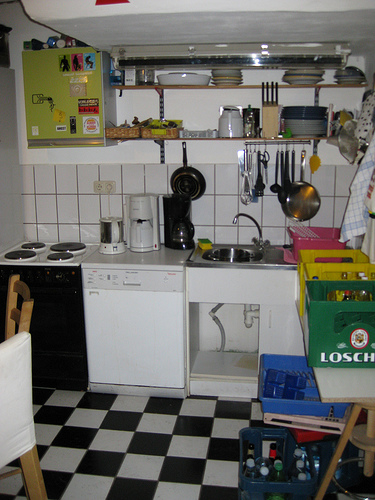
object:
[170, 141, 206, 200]
frying pan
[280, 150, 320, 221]
pot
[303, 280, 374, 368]
crate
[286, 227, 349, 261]
dish rack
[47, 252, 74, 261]
burner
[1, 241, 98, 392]
stove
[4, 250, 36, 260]
burner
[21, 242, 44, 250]
burner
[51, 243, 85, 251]
burner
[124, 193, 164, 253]
coffee pot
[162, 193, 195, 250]
coffee pot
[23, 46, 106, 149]
cabinet door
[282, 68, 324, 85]
bowls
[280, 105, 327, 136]
plates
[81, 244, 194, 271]
counter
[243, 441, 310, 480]
bottles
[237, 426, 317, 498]
crate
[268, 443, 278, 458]
bottle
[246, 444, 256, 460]
bottle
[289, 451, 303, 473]
bottle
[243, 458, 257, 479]
bottle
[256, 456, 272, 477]
bottle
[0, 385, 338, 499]
floor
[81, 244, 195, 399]
dishwasher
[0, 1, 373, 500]
kitchen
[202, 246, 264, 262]
sink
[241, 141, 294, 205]
utensils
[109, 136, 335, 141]
shelf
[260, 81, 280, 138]
knife set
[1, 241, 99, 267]
top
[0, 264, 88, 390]
oven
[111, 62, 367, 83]
dishware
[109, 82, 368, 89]
shelf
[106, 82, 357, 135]
dishware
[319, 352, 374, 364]
losch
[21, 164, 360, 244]
backsplash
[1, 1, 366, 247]
wall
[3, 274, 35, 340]
chair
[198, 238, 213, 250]
sponge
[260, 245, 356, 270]
counter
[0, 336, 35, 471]
back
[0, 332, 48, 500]
chair